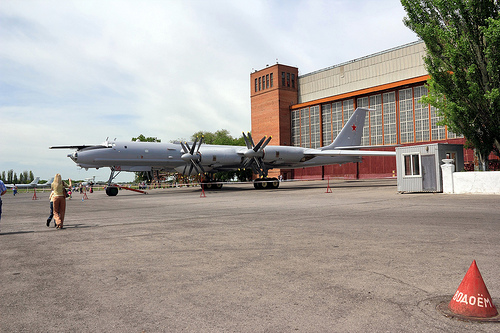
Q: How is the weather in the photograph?
A: It is cloudy.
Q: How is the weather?
A: It is cloudy.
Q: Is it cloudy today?
A: Yes, it is cloudy.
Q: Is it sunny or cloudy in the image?
A: It is cloudy.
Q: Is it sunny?
A: No, it is cloudy.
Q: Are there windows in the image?
A: Yes, there is a window.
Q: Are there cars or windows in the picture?
A: Yes, there is a window.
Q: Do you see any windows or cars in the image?
A: Yes, there is a window.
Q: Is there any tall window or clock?
A: Yes, there is a tall window.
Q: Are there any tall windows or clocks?
A: Yes, there is a tall window.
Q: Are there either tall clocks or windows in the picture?
A: Yes, there is a tall window.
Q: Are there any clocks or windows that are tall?
A: Yes, the window is tall.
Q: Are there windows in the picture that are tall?
A: Yes, there is a window that is tall.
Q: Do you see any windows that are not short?
A: Yes, there is a tall window.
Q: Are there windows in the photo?
A: Yes, there is a window.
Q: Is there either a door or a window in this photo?
A: Yes, there is a window.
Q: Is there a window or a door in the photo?
A: Yes, there is a window.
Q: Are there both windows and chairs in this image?
A: No, there is a window but no chairs.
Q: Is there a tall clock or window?
A: Yes, there is a tall window.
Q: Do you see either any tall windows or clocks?
A: Yes, there is a tall window.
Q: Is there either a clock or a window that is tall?
A: Yes, the window is tall.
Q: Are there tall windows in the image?
A: Yes, there is a tall window.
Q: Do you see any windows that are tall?
A: Yes, there is a window that is tall.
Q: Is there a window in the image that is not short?
A: Yes, there is a tall window.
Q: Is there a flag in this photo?
A: No, there are no flags.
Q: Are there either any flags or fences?
A: No, there are no flags or fences.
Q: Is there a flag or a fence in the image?
A: No, there are no flags or fences.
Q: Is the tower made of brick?
A: Yes, the tower is made of brick.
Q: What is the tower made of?
A: The tower is made of brick.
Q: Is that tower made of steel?
A: No, the tower is made of brick.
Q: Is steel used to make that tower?
A: No, the tower is made of brick.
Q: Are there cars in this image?
A: No, there are no cars.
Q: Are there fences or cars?
A: No, there are no cars or fences.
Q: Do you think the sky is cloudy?
A: Yes, the sky is cloudy.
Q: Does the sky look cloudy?
A: Yes, the sky is cloudy.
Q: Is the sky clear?
A: No, the sky is cloudy.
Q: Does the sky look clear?
A: No, the sky is cloudy.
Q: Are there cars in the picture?
A: No, there are no cars.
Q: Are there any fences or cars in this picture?
A: No, there are no cars or fences.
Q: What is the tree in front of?
A: The tree is in front of the building.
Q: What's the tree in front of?
A: The tree is in front of the building.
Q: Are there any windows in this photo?
A: Yes, there is a window.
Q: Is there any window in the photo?
A: Yes, there is a window.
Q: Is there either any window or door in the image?
A: Yes, there is a window.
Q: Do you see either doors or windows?
A: Yes, there is a window.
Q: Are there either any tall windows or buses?
A: Yes, there is a tall window.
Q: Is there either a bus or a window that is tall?
A: Yes, the window is tall.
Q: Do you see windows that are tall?
A: Yes, there is a tall window.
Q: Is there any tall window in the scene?
A: Yes, there is a tall window.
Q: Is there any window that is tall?
A: Yes, there is a window that is tall.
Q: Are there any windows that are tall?
A: Yes, there is a window that is tall.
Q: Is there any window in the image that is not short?
A: Yes, there is a tall window.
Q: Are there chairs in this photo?
A: No, there are no chairs.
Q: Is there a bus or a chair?
A: No, there are no chairs or buses.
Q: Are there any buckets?
A: No, there are no buckets.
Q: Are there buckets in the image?
A: No, there are no buckets.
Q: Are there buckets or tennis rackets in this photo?
A: No, there are no buckets or tennis rackets.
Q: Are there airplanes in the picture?
A: Yes, there is an airplane.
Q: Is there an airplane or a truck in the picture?
A: Yes, there is an airplane.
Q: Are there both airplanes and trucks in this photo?
A: No, there is an airplane but no trucks.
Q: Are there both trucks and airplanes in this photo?
A: No, there is an airplane but no trucks.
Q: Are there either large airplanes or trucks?
A: Yes, there is a large airplane.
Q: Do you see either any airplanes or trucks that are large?
A: Yes, the airplane is large.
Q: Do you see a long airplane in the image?
A: Yes, there is a long airplane.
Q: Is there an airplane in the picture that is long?
A: Yes, there is an airplane that is long.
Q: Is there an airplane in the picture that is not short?
A: Yes, there is a long airplane.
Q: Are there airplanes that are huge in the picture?
A: Yes, there is a huge airplane.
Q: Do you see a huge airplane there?
A: Yes, there is a huge airplane.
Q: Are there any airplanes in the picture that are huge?
A: Yes, there is an airplane that is huge.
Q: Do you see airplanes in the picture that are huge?
A: Yes, there is an airplane that is huge.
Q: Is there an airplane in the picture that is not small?
A: Yes, there is a huge airplane.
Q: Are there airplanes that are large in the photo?
A: Yes, there is a large airplane.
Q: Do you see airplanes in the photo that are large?
A: Yes, there is an airplane that is large.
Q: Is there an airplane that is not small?
A: Yes, there is a large airplane.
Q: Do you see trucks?
A: No, there are no trucks.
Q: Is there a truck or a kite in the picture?
A: No, there are no trucks or kites.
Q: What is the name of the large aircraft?
A: The aircraft is an airplane.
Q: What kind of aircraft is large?
A: The aircraft is an airplane.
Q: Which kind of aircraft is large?
A: The aircraft is an airplane.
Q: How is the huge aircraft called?
A: The aircraft is an airplane.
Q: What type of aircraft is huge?
A: The aircraft is an airplane.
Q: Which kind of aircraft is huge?
A: The aircraft is an airplane.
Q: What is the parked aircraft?
A: The aircraft is an airplane.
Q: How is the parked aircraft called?
A: The aircraft is an airplane.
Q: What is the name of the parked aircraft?
A: The aircraft is an airplane.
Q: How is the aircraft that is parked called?
A: The aircraft is an airplane.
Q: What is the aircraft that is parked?
A: The aircraft is an airplane.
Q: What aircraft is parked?
A: The aircraft is an airplane.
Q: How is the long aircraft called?
A: The aircraft is an airplane.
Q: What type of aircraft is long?
A: The aircraft is an airplane.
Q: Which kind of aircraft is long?
A: The aircraft is an airplane.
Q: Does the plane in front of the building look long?
A: Yes, the airplane is long.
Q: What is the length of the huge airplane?
A: The plane is long.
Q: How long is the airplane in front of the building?
A: The airplane is long.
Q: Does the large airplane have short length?
A: No, the plane is long.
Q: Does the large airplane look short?
A: No, the plane is long.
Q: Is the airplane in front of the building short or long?
A: The airplane is long.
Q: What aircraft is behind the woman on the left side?
A: The aircraft is an airplane.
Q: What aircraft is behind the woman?
A: The aircraft is an airplane.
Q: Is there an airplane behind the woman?
A: Yes, there is an airplane behind the woman.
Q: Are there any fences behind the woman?
A: No, there is an airplane behind the woman.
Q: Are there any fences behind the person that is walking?
A: No, there is an airplane behind the woman.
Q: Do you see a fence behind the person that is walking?
A: No, there is an airplane behind the woman.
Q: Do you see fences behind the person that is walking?
A: No, there is an airplane behind the woman.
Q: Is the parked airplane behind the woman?
A: Yes, the plane is behind the woman.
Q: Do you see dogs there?
A: No, there are no dogs.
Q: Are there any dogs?
A: No, there are no dogs.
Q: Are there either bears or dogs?
A: No, there are no dogs or bears.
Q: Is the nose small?
A: Yes, the nose is small.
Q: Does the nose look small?
A: Yes, the nose is small.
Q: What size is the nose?
A: The nose is small.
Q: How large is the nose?
A: The nose is small.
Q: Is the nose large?
A: No, the nose is small.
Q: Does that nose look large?
A: No, the nose is small.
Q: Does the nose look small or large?
A: The nose is small.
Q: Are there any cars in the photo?
A: No, there are no cars.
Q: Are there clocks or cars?
A: No, there are no cars or clocks.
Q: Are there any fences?
A: No, there are no fences.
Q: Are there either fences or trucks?
A: No, there are no fences or trucks.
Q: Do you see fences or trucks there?
A: No, there are no fences or trucks.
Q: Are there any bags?
A: No, there are no bags.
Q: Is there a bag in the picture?
A: No, there are no bags.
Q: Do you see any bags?
A: No, there are no bags.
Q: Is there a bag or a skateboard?
A: No, there are no bags or skateboards.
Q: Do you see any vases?
A: No, there are no vases.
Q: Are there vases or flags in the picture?
A: No, there are no vases or flags.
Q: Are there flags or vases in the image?
A: No, there are no vases or flags.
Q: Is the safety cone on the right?
A: Yes, the safety cone is on the right of the image.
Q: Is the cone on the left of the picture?
A: No, the cone is on the right of the image.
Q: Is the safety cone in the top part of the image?
A: No, the safety cone is in the bottom of the image.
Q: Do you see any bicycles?
A: No, there are no bicycles.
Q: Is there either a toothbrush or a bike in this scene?
A: No, there are no bikes or toothbrushes.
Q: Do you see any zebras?
A: No, there are no zebras.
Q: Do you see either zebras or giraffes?
A: No, there are no zebras or giraffes.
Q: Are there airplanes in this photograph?
A: Yes, there is an airplane.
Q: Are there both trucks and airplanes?
A: No, there is an airplane but no trucks.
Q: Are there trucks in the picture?
A: No, there are no trucks.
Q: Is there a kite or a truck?
A: No, there are no trucks or kites.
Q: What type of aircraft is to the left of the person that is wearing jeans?
A: The aircraft is an airplane.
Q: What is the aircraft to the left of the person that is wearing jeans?
A: The aircraft is an airplane.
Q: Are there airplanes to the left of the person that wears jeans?
A: Yes, there is an airplane to the left of the person.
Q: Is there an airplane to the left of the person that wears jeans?
A: Yes, there is an airplane to the left of the person.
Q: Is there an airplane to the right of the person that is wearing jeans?
A: No, the airplane is to the left of the person.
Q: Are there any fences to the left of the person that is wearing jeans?
A: No, there is an airplane to the left of the person.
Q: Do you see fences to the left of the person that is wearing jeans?
A: No, there is an airplane to the left of the person.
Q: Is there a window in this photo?
A: Yes, there is a window.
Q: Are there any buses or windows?
A: Yes, there is a window.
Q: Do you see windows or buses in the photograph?
A: Yes, there is a window.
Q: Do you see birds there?
A: No, there are no birds.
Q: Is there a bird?
A: No, there are no birds.